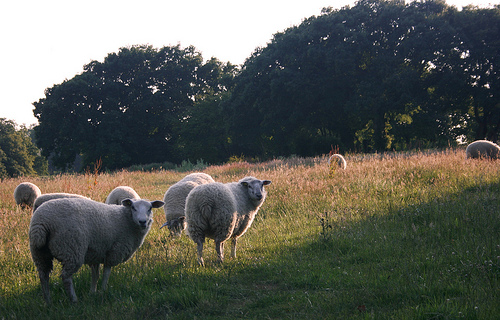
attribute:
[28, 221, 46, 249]
tail — stubby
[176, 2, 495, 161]
tree — big, green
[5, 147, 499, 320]
field — grass, green, grassy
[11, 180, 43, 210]
sheep — grazing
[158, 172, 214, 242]
sheep — grazing, here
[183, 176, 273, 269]
sheep — furry, wooly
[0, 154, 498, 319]
grass — brown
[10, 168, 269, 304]
sheep — staring at camera, here, enjoying meal, eating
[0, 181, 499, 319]
shadows — here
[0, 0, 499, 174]
trees — here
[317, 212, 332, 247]
flower patch — here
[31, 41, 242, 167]
tree — big, green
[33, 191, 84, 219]
sheep — grazing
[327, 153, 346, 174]
sheep — grazing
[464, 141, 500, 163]
sheep — grazing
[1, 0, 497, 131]
sky — clear, blue, white, bright, here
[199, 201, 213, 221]
tail — stubby